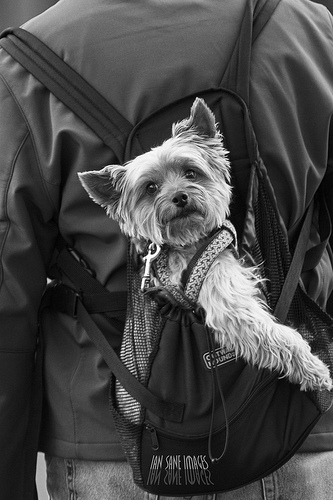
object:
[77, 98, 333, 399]
dog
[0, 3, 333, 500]
backpack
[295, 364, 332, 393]
paw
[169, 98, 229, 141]
ear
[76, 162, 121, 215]
ear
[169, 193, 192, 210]
nose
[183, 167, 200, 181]
eye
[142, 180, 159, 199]
eye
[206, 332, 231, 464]
cord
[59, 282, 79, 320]
buckle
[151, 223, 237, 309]
leash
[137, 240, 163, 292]
clasp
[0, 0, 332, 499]
man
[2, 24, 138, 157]
strap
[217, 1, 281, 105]
strap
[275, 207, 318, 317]
strap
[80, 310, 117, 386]
strap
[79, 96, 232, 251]
head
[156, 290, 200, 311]
tag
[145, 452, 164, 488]
words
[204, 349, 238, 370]
words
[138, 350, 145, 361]
netting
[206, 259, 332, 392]
leg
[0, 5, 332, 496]
jacket